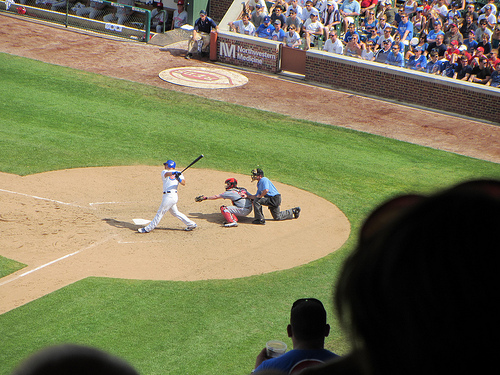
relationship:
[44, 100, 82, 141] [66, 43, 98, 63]
grass around field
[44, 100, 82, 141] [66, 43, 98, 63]
grass on field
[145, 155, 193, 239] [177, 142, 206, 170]
player holding bat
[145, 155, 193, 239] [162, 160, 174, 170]
player wearing helmet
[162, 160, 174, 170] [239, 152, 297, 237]
helmet on man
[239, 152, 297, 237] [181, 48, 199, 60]
man wearing shoe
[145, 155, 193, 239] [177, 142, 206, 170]
player with bat